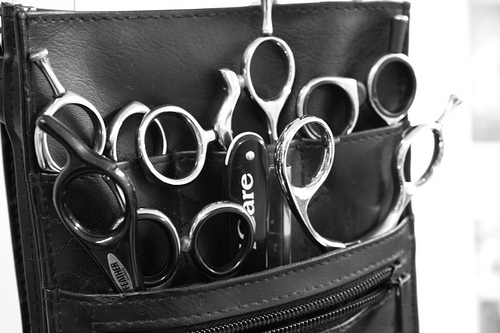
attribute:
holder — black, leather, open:
[1, 1, 420, 333]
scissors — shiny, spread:
[273, 94, 463, 253]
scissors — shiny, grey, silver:
[297, 14, 419, 138]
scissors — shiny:
[135, 1, 295, 188]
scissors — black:
[39, 115, 141, 295]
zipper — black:
[155, 258, 411, 333]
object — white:
[472, 142, 499, 300]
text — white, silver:
[238, 173, 257, 252]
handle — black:
[91, 236, 144, 294]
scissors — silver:
[102, 173, 256, 293]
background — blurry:
[410, 1, 499, 333]